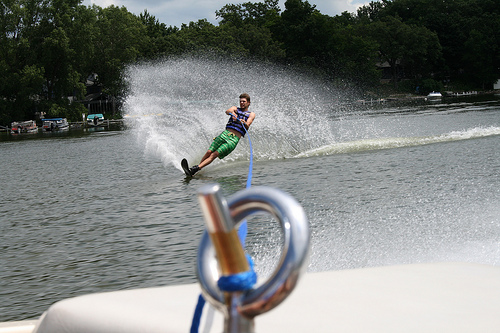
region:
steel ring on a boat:
[186, 180, 318, 332]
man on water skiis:
[168, 84, 265, 189]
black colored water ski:
[178, 154, 193, 181]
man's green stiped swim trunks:
[201, 126, 242, 162]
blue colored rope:
[214, 110, 271, 305]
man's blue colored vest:
[222, 104, 249, 139]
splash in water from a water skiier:
[108, 46, 372, 171]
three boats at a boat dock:
[7, 113, 109, 136]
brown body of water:
[1, 103, 498, 321]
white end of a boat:
[4, 260, 499, 330]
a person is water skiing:
[113, 50, 355, 182]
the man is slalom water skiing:
[159, 121, 248, 181]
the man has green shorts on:
[206, 129, 238, 157]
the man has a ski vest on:
[179, 90, 265, 142]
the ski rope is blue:
[217, 120, 257, 304]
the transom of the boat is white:
[17, 246, 494, 330]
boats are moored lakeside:
[8, 107, 118, 138]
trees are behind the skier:
[9, 8, 496, 138]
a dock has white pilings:
[448, 84, 487, 103]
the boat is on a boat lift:
[78, 108, 115, 137]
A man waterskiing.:
[180, 89, 260, 186]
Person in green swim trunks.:
[177, 91, 257, 181]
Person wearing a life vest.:
[177, 90, 257, 182]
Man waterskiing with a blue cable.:
[175, 89, 317, 331]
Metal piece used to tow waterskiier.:
[184, 169, 309, 331]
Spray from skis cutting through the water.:
[122, 46, 375, 181]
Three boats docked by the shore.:
[7, 109, 109, 137]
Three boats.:
[8, 112, 107, 139]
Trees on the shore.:
[2, 0, 498, 115]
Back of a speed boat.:
[1, 251, 498, 331]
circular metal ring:
[166, 166, 321, 316]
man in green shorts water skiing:
[146, 74, 271, 192]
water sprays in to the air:
[103, 47, 498, 163]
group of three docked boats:
[7, 103, 116, 146]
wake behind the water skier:
[199, 122, 499, 178]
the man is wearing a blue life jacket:
[191, 78, 276, 143]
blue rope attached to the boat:
[226, 104, 263, 312]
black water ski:
[164, 147, 201, 193]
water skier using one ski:
[148, 53, 276, 202]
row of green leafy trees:
[6, 5, 498, 110]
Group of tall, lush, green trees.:
[47, 4, 118, 108]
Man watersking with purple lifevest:
[122, 59, 306, 195]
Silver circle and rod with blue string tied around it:
[189, 189, 321, 309]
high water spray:
[116, 60, 181, 180]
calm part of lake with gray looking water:
[25, 170, 125, 263]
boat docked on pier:
[73, 100, 114, 138]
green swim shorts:
[205, 129, 242, 160]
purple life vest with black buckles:
[226, 109, 252, 140]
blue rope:
[243, 141, 258, 185]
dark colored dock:
[345, 93, 402, 110]